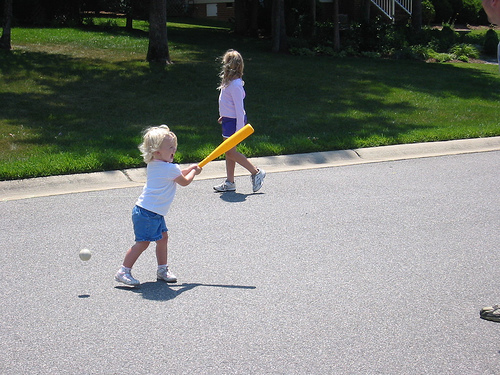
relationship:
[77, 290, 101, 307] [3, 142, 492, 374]
shadow on top of pavement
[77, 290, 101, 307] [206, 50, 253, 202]
shadow of girl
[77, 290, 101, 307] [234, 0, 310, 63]
shadow of trees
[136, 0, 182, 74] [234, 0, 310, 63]
tree of trees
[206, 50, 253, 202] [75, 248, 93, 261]
girl missing baseball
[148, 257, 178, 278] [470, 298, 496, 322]
foot of person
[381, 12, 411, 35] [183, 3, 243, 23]
steps on home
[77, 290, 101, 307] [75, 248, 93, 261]
shadow of baseball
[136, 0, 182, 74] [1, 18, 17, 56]
tree of tree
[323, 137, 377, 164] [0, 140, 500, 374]
curb of pavement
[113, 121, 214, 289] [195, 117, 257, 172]
kids swinging bat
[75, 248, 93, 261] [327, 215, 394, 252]
baseball hitting ground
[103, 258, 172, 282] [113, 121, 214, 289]
sneakers on kids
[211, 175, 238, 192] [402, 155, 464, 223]
shoe on right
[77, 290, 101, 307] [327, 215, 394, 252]
shadow on ground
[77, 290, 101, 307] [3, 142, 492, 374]
shadow on pavement